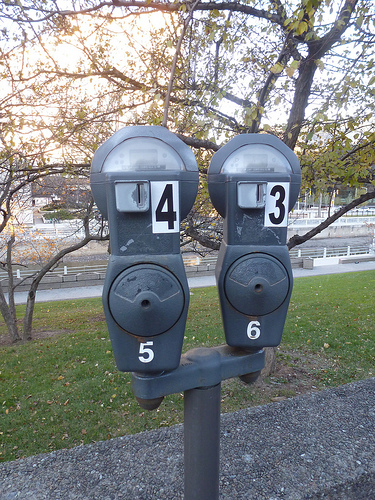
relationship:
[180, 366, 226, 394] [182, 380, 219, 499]
edge of a pole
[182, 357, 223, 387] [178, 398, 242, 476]
edge of a post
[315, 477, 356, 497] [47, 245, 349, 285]
edge of road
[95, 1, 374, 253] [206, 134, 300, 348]
tree behind meter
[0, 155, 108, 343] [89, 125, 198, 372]
tree behind machine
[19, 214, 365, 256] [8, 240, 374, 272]
water behind fence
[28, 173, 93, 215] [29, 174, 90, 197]
building with roof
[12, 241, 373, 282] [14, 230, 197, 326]
fence with rails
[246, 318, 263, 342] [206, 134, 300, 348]
number on meter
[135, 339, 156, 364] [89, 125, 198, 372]
number on machine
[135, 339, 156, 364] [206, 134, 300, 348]
number on meter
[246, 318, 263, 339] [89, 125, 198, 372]
number on machine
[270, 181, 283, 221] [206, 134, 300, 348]
number on meter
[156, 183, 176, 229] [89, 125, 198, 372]
four on machine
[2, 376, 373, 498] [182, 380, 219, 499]
wall near pole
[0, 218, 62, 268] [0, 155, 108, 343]
leaves on tree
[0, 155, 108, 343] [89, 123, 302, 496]
tree left of parking meter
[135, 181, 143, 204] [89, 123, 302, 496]
coin slot on parking meter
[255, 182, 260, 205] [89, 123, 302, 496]
coin slot on parking meter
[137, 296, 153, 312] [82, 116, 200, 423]
hole in parking meter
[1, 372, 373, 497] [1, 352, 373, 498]
gravel in sidewalk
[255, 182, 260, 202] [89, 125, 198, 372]
coin slot on machine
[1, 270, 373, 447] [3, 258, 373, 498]
grass on ground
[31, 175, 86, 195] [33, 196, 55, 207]
roof on house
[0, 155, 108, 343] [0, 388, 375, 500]
tree at floor